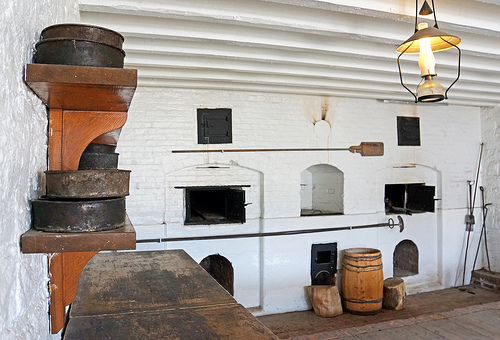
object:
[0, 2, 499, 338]
bakery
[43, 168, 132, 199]
pan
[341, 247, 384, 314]
barrel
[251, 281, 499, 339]
floor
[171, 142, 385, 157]
tool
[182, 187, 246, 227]
oven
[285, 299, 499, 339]
rug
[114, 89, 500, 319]
wall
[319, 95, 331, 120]
burn marks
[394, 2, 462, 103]
lamp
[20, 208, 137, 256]
shelf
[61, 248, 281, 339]
table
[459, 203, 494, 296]
tools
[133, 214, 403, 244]
rod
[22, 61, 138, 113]
shelves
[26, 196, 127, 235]
pans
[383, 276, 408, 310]
stump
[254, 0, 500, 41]
beams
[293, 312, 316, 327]
bricks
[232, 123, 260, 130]
bricks